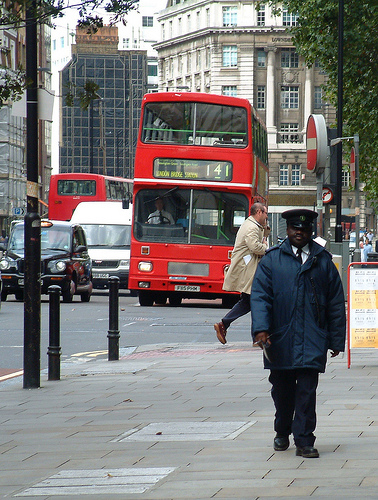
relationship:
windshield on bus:
[116, 86, 275, 302] [85, 70, 278, 298]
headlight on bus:
[129, 250, 233, 285] [118, 76, 249, 265]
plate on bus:
[170, 282, 202, 294] [118, 196, 243, 308]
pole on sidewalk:
[15, 3, 48, 215] [99, 400, 262, 486]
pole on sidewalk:
[15, 3, 48, 215] [78, 426, 211, 481]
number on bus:
[201, 158, 237, 180] [203, 159, 234, 183]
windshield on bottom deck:
[116, 86, 275, 302] [132, 194, 244, 268]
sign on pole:
[300, 112, 338, 177] [294, 132, 348, 254]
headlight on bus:
[129, 250, 233, 285] [123, 86, 277, 318]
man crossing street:
[211, 202, 272, 343] [4, 286, 363, 378]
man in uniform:
[242, 209, 357, 461] [252, 238, 348, 459]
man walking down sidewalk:
[242, 209, 357, 461] [1, 346, 362, 498]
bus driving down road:
[203, 159, 234, 183] [1, 294, 365, 381]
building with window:
[153, 0, 332, 191] [220, 45, 305, 110]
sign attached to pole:
[300, 112, 338, 177] [313, 172, 330, 245]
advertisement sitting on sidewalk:
[343, 258, 377, 361] [1, 346, 362, 498]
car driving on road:
[0, 217, 90, 302] [1, 296, 248, 380]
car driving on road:
[68, 197, 138, 295] [1, 296, 248, 380]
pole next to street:
[15, 3, 48, 215] [1, 285, 255, 381]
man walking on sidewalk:
[211, 202, 272, 343] [1, 346, 362, 498]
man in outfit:
[242, 209, 357, 461] [240, 200, 356, 470]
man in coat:
[211, 202, 272, 343] [217, 209, 270, 298]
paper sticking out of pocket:
[242, 251, 254, 266] [245, 257, 262, 268]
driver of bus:
[140, 199, 175, 226] [203, 159, 234, 183]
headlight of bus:
[129, 250, 233, 285] [123, 86, 277, 318]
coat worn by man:
[223, 216, 263, 298] [211, 202, 272, 343]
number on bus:
[206, 163, 229, 178] [123, 86, 277, 318]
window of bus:
[143, 99, 258, 160] [123, 86, 277, 318]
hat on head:
[275, 207, 319, 230] [275, 204, 323, 254]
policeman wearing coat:
[244, 195, 352, 458] [248, 235, 349, 373]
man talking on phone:
[211, 202, 272, 343] [263, 217, 271, 228]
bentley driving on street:
[3, 211, 96, 303] [1, 285, 255, 381]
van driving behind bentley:
[69, 199, 128, 297] [1, 217, 93, 302]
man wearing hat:
[251, 206, 346, 461] [275, 207, 319, 230]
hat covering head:
[275, 207, 319, 230] [283, 214, 313, 247]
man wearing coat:
[242, 209, 357, 461] [248, 235, 349, 373]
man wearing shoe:
[211, 202, 272, 343] [212, 320, 228, 344]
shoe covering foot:
[212, 320, 228, 344] [214, 319, 227, 344]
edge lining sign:
[306, 115, 317, 173] [300, 112, 338, 177]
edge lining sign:
[304, 148, 317, 170] [300, 112, 338, 177]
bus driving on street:
[203, 159, 234, 183] [1, 285, 255, 381]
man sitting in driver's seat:
[145, 198, 174, 225] [142, 214, 185, 237]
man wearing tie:
[251, 206, 346, 461] [292, 248, 307, 263]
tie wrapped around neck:
[292, 248, 307, 263] [287, 241, 310, 251]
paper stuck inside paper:
[242, 251, 254, 266] [243, 254, 252, 266]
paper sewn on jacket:
[243, 254, 252, 266] [212, 200, 271, 344]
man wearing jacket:
[211, 202, 272, 343] [212, 200, 271, 344]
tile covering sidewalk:
[119, 343, 261, 358] [1, 346, 362, 498]